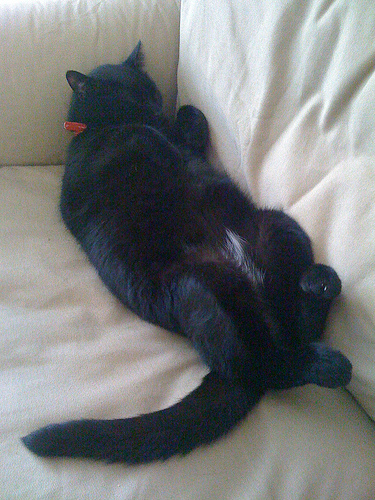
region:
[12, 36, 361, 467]
A cat on his back resting on a couch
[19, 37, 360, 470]
A cat on his back resting on a couch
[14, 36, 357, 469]
A cat on his back resting on a couch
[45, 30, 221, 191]
Cat laying on the sofa sleeping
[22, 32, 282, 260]
Cat laying on the sofa sleeping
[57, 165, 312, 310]
Cat laying on the sofa sleeping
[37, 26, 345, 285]
Cat laying on the sofa sleeping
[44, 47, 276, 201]
Cat laying on the sofa sleeping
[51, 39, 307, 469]
Cat laying on the sofa sleeping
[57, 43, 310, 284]
Cat laying on the sofa sleeping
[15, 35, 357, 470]
A cat resting on its back on a sofa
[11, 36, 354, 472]
A cat resting on its back on a sofa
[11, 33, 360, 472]
A cat resting on its back on a sofa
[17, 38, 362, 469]
A cat resting on its back on a sofa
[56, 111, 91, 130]
a red tag on the cat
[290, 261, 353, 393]
two paws in the air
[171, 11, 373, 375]
the back of a white sofa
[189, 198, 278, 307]
a section of white fur on the cat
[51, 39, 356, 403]
a sleeping black cat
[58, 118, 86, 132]
part of the cat's collar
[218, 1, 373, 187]
wrinkles in a fabric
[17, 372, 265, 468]
a black cat's tail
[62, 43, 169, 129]
the cat has it's eyes close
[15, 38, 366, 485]
the cat is face-up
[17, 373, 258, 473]
long tail of cat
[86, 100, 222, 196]
front legs of cat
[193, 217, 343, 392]
back legs of cat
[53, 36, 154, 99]
pointy ears of cat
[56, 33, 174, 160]
red tag on black cat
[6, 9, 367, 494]
cat lying on couch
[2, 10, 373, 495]
couch is color white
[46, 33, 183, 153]
the head of cat